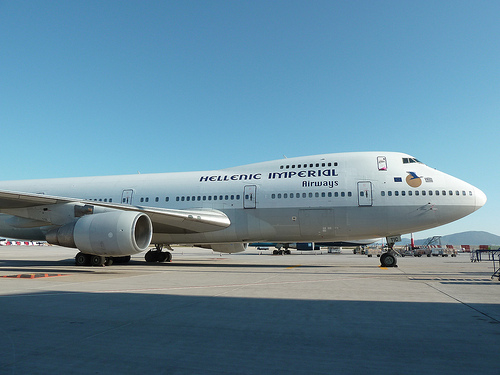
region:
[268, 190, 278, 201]
the window of a plane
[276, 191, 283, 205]
the window of a plane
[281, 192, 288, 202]
the window of a plane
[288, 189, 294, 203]
the window of a plane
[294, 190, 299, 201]
the window of a plane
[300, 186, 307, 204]
the window of a plane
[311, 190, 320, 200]
the window of a plane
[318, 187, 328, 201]
the window of a plane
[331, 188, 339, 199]
the window of a plane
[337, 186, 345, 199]
the window of a plane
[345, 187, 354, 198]
A window on a plane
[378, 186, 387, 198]
A window on a plane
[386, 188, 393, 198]
A window on a plane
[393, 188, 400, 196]
A window on a plane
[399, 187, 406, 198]
A window on a plane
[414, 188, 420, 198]
A window on a plane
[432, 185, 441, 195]
A window on a plane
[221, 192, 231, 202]
A window on a plane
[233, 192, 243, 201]
A window on a plane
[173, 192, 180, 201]
A window on a plane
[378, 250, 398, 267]
the wheel of a plane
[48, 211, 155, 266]
the engine of a plane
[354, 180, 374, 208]
the door of a plane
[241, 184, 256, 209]
the door of a plane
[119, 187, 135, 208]
the door of a plane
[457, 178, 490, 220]
the tip of a plane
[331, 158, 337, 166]
the window of a plane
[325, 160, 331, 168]
the window of a plane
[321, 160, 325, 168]
the window of a plane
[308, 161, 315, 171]
the window of a plane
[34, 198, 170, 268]
Large jet engine on a plane.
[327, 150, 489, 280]
cock pit on a large jetliner.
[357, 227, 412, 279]
landing gear on a large jet.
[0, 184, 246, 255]
right wing on a large jet.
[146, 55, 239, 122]
section of clear blue sky.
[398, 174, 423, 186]
emblem painted on the side of a jet.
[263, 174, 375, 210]
windows on the side of a jet.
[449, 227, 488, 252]
hillside off in the distance.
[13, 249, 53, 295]
Orange section painted on ground.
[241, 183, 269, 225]
loading door on the side of a jet.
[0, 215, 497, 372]
hangar in the airport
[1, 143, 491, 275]
commercial plane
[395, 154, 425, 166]
window of the cockpit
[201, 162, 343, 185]
hellenic imperial sign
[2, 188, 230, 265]
right wing of the plane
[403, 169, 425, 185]
a blue bird sign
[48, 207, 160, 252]
right blades under the wing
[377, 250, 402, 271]
front wheel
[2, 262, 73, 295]
orange marks on the floor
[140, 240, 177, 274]
landing gear